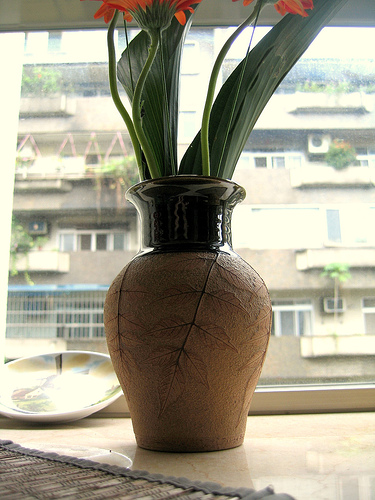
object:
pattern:
[148, 255, 244, 416]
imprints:
[214, 260, 257, 292]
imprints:
[147, 251, 212, 272]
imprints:
[204, 286, 251, 318]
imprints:
[144, 282, 198, 309]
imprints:
[192, 317, 239, 352]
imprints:
[138, 313, 188, 344]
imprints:
[182, 347, 210, 387]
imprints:
[136, 341, 180, 365]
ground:
[0, 415, 375, 500]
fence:
[7, 292, 105, 340]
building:
[6, 31, 373, 376]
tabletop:
[0, 409, 374, 498]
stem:
[131, 30, 165, 179]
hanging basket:
[323, 154, 353, 171]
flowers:
[348, 144, 352, 149]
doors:
[79, 233, 92, 249]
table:
[0, 419, 375, 500]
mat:
[0, 439, 289, 500]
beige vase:
[104, 181, 274, 454]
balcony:
[4, 285, 109, 355]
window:
[1, 14, 375, 383]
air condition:
[322, 295, 346, 313]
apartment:
[232, 199, 374, 260]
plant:
[320, 260, 351, 307]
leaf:
[156, 358, 186, 424]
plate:
[0, 348, 125, 421]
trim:
[0, 437, 299, 499]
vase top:
[125, 174, 244, 255]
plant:
[25, 65, 60, 95]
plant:
[17, 150, 33, 164]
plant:
[98, 153, 137, 187]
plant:
[12, 223, 33, 256]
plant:
[325, 136, 357, 169]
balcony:
[17, 92, 74, 116]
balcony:
[15, 170, 75, 192]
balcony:
[7, 250, 71, 273]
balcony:
[289, 160, 374, 190]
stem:
[105, 7, 145, 181]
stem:
[200, 3, 264, 174]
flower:
[264, 0, 319, 17]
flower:
[91, 0, 205, 30]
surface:
[0, 407, 374, 499]